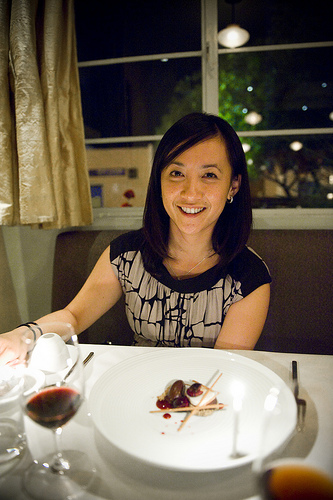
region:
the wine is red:
[28, 379, 92, 427]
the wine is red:
[15, 360, 99, 436]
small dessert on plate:
[168, 357, 231, 463]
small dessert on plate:
[131, 371, 229, 439]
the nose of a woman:
[176, 174, 200, 204]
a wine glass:
[14, 322, 98, 499]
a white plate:
[91, 344, 299, 477]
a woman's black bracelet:
[15, 318, 39, 346]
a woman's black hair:
[140, 110, 257, 270]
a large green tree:
[151, 66, 266, 184]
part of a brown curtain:
[0, 0, 96, 231]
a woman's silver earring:
[225, 195, 233, 205]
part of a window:
[209, 3, 332, 208]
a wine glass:
[21, 337, 82, 395]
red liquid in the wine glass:
[26, 388, 78, 420]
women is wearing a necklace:
[162, 260, 201, 283]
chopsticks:
[183, 401, 198, 419]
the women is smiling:
[176, 202, 203, 217]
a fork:
[285, 355, 310, 403]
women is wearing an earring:
[226, 194, 236, 203]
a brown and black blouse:
[138, 287, 219, 342]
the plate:
[101, 386, 137, 423]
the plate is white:
[191, 426, 220, 459]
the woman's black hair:
[142, 111, 253, 266]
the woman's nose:
[179, 189, 203, 202]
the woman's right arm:
[22, 245, 124, 342]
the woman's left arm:
[213, 281, 271, 349]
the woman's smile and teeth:
[174, 203, 208, 218]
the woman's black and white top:
[109, 226, 274, 347]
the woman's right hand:
[0, 331, 29, 362]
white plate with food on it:
[85, 348, 303, 475]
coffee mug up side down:
[30, 330, 79, 375]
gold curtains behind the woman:
[0, 0, 94, 230]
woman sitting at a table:
[0, 108, 303, 364]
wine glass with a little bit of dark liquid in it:
[21, 333, 96, 499]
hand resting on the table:
[1, 322, 41, 371]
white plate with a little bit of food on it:
[91, 349, 312, 475]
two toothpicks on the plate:
[149, 368, 230, 434]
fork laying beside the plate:
[286, 356, 309, 430]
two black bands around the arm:
[13, 314, 53, 355]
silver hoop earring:
[226, 193, 233, 203]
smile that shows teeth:
[174, 201, 219, 222]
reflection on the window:
[218, 21, 250, 51]